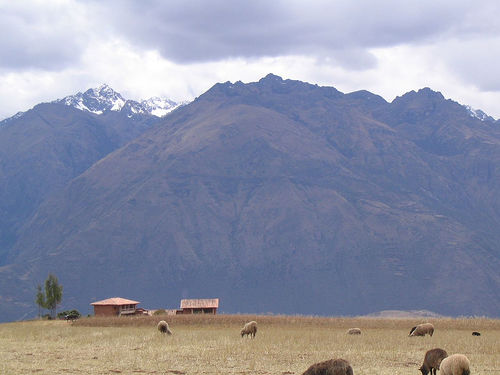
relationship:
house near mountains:
[81, 293, 228, 323] [0, 72, 499, 318]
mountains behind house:
[0, 72, 499, 318] [81, 293, 228, 323]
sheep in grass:
[153, 321, 489, 372] [3, 321, 498, 372]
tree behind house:
[31, 272, 81, 321] [81, 293, 228, 323]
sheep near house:
[153, 321, 489, 372] [81, 293, 228, 323]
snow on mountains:
[55, 79, 181, 111] [0, 72, 499, 318]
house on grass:
[81, 293, 228, 323] [3, 321, 498, 372]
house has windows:
[81, 293, 228, 323] [111, 305, 217, 314]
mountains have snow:
[0, 72, 499, 318] [55, 79, 181, 111]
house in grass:
[81, 293, 228, 323] [3, 321, 498, 372]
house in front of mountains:
[81, 293, 228, 323] [0, 72, 499, 318]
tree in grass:
[31, 272, 81, 321] [3, 321, 498, 372]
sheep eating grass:
[153, 321, 489, 372] [3, 321, 498, 372]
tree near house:
[31, 272, 81, 321] [81, 293, 228, 323]